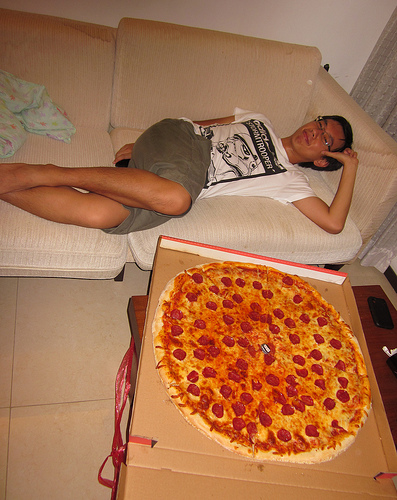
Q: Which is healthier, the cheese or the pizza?
A: The cheese is healthier than the pizza.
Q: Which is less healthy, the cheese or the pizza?
A: The pizza is less healthy than the cheese.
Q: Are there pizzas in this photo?
A: Yes, there is a pizza.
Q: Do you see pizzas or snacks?
A: Yes, there is a pizza.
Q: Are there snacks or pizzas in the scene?
A: Yes, there is a pizza.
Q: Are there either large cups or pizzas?
A: Yes, there is a large pizza.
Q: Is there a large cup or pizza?
A: Yes, there is a large pizza.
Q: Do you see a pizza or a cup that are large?
A: Yes, the pizza is large.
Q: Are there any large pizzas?
A: Yes, there is a large pizza.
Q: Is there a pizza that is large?
A: Yes, there is a pizza that is large.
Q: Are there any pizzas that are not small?
A: Yes, there is a large pizza.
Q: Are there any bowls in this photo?
A: No, there are no bowls.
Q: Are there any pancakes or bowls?
A: No, there are no bowls or pancakes.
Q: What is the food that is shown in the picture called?
A: The food is a pizza.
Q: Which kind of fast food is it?
A: The food is a pizza.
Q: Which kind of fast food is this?
A: That is a pizza.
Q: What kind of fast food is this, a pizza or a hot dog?
A: That is a pizza.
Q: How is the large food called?
A: The food is a pizza.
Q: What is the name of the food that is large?
A: The food is a pizza.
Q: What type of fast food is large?
A: The fast food is a pizza.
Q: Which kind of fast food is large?
A: The fast food is a pizza.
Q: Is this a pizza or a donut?
A: This is a pizza.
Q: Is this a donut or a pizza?
A: This is a pizza.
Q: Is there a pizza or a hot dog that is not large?
A: No, there is a pizza but it is large.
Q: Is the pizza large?
A: Yes, the pizza is large.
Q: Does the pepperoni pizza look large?
A: Yes, the pizza is large.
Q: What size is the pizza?
A: The pizza is large.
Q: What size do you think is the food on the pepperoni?
A: The pizza is large.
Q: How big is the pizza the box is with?
A: The pizza is large.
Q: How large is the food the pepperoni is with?
A: The pizza is large.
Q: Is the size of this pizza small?
A: No, the pizza is large.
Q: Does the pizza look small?
A: No, the pizza is large.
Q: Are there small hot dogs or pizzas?
A: No, there is a pizza but it is large.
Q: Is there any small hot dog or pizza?
A: No, there is a pizza but it is large.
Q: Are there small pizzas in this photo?
A: No, there is a pizza but it is large.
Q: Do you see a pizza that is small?
A: No, there is a pizza but it is large.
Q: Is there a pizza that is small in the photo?
A: No, there is a pizza but it is large.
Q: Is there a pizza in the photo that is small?
A: No, there is a pizza but it is large.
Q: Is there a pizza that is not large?
A: No, there is a pizza but it is large.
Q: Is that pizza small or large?
A: The pizza is large.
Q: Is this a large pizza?
A: Yes, this is a large pizza.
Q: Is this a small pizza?
A: No, this is a large pizza.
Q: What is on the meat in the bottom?
A: The pizza is on the pepperoni.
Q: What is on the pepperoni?
A: The pizza is on the pepperoni.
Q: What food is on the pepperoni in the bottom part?
A: The food is a pizza.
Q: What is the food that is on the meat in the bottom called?
A: The food is a pizza.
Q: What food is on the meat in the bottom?
A: The food is a pizza.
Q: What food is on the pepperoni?
A: The food is a pizza.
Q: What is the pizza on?
A: The pizza is on the pepperoni.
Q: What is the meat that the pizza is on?
A: The meat is pepperoni.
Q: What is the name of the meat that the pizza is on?
A: The meat is pepperoni.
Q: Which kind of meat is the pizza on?
A: The pizza is on the pepperoni.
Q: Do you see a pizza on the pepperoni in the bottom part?
A: Yes, there is a pizza on the pepperoni.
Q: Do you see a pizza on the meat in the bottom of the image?
A: Yes, there is a pizza on the pepperoni.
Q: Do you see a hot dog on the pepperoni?
A: No, there is a pizza on the pepperoni.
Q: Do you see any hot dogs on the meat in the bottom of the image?
A: No, there is a pizza on the pepperoni.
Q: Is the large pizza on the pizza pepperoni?
A: Yes, the pizza is on the pepperoni.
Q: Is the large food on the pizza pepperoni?
A: Yes, the pizza is on the pepperoni.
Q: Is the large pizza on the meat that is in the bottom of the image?
A: Yes, the pizza is on the pepperoni.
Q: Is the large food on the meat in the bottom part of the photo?
A: Yes, the pizza is on the pepperoni.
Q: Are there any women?
A: No, there are no women.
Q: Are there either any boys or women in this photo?
A: No, there are no women or boys.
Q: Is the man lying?
A: Yes, the man is lying.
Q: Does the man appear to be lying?
A: Yes, the man is lying.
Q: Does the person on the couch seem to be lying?
A: Yes, the man is lying.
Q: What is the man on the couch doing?
A: The man is lying.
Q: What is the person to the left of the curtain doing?
A: The man is lying.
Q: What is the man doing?
A: The man is lying.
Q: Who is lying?
A: The man is lying.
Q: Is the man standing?
A: No, the man is lying.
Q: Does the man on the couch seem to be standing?
A: No, the man is lying.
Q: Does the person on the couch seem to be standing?
A: No, the man is lying.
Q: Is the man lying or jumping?
A: The man is lying.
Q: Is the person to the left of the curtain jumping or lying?
A: The man is lying.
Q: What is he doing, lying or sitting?
A: The man is lying.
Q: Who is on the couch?
A: The man is on the couch.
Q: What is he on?
A: The man is on the couch.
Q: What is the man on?
A: The man is on the couch.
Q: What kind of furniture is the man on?
A: The man is on the couch.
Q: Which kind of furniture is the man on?
A: The man is on the couch.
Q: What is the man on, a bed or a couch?
A: The man is on a couch.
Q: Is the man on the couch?
A: Yes, the man is on the couch.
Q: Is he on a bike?
A: No, the man is on the couch.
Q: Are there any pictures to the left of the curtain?
A: No, there is a man to the left of the curtain.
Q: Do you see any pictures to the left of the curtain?
A: No, there is a man to the left of the curtain.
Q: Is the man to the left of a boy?
A: No, the man is to the left of the curtain.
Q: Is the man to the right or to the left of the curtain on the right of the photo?
A: The man is to the left of the curtain.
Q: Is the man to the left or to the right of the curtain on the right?
A: The man is to the left of the curtain.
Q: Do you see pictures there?
A: No, there are no pictures.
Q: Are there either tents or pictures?
A: No, there are no pictures or tents.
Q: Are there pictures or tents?
A: No, there are no pictures or tents.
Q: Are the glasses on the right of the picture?
A: Yes, the glasses are on the right of the image.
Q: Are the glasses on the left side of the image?
A: No, the glasses are on the right of the image.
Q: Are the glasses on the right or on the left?
A: The glasses are on the right of the image.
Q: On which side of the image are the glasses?
A: The glasses are on the right of the image.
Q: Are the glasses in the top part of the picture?
A: Yes, the glasses are in the top of the image.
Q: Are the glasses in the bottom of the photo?
A: No, the glasses are in the top of the image.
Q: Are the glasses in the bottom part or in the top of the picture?
A: The glasses are in the top of the image.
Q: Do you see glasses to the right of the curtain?
A: No, the glasses are to the left of the curtain.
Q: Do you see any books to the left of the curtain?
A: No, there are glasses to the left of the curtain.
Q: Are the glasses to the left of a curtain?
A: Yes, the glasses are to the left of a curtain.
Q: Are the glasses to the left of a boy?
A: No, the glasses are to the left of a curtain.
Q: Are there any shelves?
A: No, there are no shelves.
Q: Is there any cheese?
A: Yes, there is cheese.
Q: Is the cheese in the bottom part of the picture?
A: Yes, the cheese is in the bottom of the image.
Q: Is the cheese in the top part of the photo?
A: No, the cheese is in the bottom of the image.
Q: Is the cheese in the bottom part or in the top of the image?
A: The cheese is in the bottom of the image.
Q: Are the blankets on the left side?
A: Yes, the blankets are on the left of the image.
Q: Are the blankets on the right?
A: No, the blankets are on the left of the image.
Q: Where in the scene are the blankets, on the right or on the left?
A: The blankets are on the left of the image.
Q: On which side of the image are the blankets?
A: The blankets are on the left of the image.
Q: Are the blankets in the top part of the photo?
A: Yes, the blankets are in the top of the image.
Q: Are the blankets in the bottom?
A: No, the blankets are in the top of the image.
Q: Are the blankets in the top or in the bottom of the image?
A: The blankets are in the top of the image.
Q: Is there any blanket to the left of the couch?
A: Yes, there are blankets to the left of the couch.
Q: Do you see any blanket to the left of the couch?
A: Yes, there are blankets to the left of the couch.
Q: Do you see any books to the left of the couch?
A: No, there are blankets to the left of the couch.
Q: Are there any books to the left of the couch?
A: No, there are blankets to the left of the couch.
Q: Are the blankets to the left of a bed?
A: No, the blankets are to the left of the couch.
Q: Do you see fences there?
A: No, there are no fences.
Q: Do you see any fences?
A: No, there are no fences.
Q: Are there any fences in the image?
A: No, there are no fences.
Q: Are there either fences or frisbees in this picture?
A: No, there are no fences or frisbees.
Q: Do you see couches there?
A: Yes, there is a couch.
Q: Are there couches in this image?
A: Yes, there is a couch.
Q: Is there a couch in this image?
A: Yes, there is a couch.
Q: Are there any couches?
A: Yes, there is a couch.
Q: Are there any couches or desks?
A: Yes, there is a couch.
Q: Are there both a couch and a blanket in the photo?
A: Yes, there are both a couch and a blanket.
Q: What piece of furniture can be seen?
A: The piece of furniture is a couch.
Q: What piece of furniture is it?
A: The piece of furniture is a couch.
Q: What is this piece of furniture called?
A: This is a couch.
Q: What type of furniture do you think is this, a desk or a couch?
A: This is a couch.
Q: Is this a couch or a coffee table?
A: This is a couch.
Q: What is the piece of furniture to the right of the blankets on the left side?
A: The piece of furniture is a couch.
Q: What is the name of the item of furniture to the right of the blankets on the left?
A: The piece of furniture is a couch.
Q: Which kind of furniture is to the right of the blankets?
A: The piece of furniture is a couch.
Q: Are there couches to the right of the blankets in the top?
A: Yes, there is a couch to the right of the blankets.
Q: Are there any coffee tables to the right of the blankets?
A: No, there is a couch to the right of the blankets.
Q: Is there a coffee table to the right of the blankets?
A: No, there is a couch to the right of the blankets.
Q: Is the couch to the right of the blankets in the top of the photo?
A: Yes, the couch is to the right of the blankets.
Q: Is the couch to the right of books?
A: No, the couch is to the right of the blankets.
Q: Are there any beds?
A: No, there are no beds.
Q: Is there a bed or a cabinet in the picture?
A: No, there are no beds or cabinets.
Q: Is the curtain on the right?
A: Yes, the curtain is on the right of the image.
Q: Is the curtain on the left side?
A: No, the curtain is on the right of the image.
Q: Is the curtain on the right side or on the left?
A: The curtain is on the right of the image.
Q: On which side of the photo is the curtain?
A: The curtain is on the right of the image.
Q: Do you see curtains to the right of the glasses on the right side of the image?
A: Yes, there is a curtain to the right of the glasses.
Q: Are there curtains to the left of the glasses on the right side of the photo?
A: No, the curtain is to the right of the glasses.